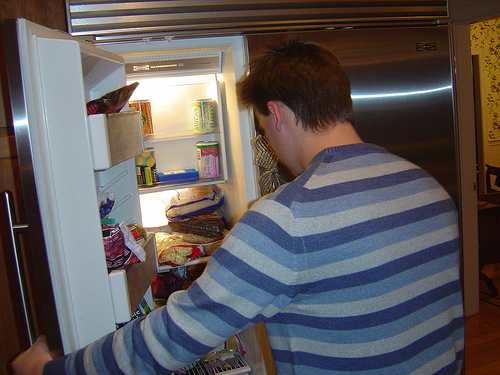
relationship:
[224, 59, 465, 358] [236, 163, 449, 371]
boy wearing sweater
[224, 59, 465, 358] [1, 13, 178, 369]
boy holding fridge door